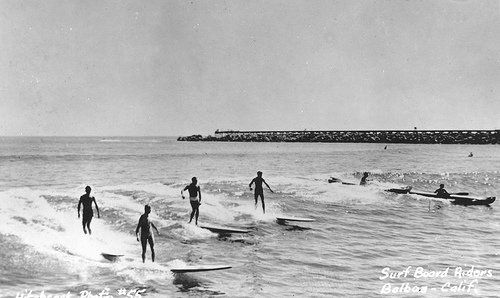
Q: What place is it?
A: It is an ocean.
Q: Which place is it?
A: It is an ocean.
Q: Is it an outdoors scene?
A: Yes, it is outdoors.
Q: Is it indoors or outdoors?
A: It is outdoors.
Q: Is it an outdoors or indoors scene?
A: It is outdoors.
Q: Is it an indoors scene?
A: No, it is outdoors.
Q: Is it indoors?
A: No, it is outdoors.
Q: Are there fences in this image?
A: No, there are no fences.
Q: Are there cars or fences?
A: No, there are no fences or cars.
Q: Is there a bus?
A: No, there are no buses.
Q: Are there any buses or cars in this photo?
A: No, there are no buses or cars.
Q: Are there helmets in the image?
A: No, there are no helmets.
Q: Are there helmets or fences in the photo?
A: No, there are no helmets or fences.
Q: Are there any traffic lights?
A: No, there are no traffic lights.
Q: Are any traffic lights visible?
A: No, there are no traffic lights.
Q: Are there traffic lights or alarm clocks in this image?
A: No, there are no traffic lights or alarm clocks.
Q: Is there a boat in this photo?
A: Yes, there is a boat.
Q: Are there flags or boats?
A: Yes, there is a boat.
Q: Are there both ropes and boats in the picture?
A: No, there is a boat but no ropes.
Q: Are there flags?
A: No, there are no flags.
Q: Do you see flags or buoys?
A: No, there are no flags or buoys.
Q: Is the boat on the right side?
A: Yes, the boat is on the right of the image.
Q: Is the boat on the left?
A: No, the boat is on the right of the image.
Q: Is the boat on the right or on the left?
A: The boat is on the right of the image.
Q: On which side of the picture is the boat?
A: The boat is on the right of the image.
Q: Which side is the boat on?
A: The boat is on the right of the image.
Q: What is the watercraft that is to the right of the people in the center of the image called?
A: The watercraft is a boat.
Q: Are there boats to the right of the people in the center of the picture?
A: Yes, there is a boat to the right of the people.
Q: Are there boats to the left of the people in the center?
A: No, the boat is to the right of the people.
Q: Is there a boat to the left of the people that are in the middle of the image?
A: No, the boat is to the right of the people.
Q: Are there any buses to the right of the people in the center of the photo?
A: No, there is a boat to the right of the people.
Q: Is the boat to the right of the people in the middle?
A: Yes, the boat is to the right of the people.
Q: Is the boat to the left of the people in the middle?
A: No, the boat is to the right of the people.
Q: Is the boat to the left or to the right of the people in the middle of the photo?
A: The boat is to the right of the people.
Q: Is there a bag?
A: No, there are no bags.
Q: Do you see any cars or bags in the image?
A: No, there are no bags or cars.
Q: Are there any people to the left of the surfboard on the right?
A: Yes, there are people to the left of the surf board.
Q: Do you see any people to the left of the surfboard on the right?
A: Yes, there are people to the left of the surf board.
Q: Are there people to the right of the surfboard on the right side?
A: No, the people are to the left of the surfboard.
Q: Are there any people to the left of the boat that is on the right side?
A: Yes, there are people to the left of the boat.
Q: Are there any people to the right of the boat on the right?
A: No, the people are to the left of the boat.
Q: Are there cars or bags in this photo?
A: No, there are no cars or bags.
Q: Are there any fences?
A: No, there are no fences.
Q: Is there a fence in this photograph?
A: No, there are no fences.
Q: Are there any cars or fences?
A: No, there are no fences or cars.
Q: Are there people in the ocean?
A: Yes, there are people in the ocean.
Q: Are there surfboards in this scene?
A: Yes, there is a surfboard.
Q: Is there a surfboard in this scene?
A: Yes, there is a surfboard.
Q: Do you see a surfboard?
A: Yes, there is a surfboard.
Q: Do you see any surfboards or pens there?
A: Yes, there is a surfboard.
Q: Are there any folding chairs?
A: No, there are no folding chairs.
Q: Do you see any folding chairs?
A: No, there are no folding chairs.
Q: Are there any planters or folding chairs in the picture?
A: No, there are no folding chairs or planters.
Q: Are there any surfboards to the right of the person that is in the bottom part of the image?
A: Yes, there is a surfboard to the right of the person.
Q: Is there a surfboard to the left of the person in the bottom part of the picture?
A: No, the surfboard is to the right of the person.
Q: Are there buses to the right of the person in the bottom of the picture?
A: No, there is a surfboard to the right of the person.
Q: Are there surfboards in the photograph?
A: Yes, there is a surfboard.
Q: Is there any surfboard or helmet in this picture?
A: Yes, there is a surfboard.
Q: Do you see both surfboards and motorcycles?
A: No, there is a surfboard but no motorcycles.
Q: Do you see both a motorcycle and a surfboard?
A: No, there is a surfboard but no motorcycles.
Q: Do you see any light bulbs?
A: No, there are no light bulbs.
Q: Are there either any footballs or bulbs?
A: No, there are no bulbs or footballs.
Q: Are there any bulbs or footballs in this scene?
A: No, there are no bulbs or footballs.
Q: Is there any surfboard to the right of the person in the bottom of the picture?
A: Yes, there is a surfboard to the right of the person.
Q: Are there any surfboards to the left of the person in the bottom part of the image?
A: No, the surfboard is to the right of the person.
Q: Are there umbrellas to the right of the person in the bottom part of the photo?
A: No, there is a surfboard to the right of the person.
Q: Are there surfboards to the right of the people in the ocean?
A: Yes, there is a surfboard to the right of the people.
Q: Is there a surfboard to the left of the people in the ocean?
A: No, the surfboard is to the right of the people.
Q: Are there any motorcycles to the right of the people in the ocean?
A: No, there is a surfboard to the right of the people.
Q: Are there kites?
A: No, there are no kites.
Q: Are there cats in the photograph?
A: No, there are no cats.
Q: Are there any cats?
A: No, there are no cats.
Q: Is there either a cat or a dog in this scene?
A: No, there are no cats or dogs.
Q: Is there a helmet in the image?
A: No, there are no helmets.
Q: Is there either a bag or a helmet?
A: No, there are no helmets or bags.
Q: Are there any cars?
A: No, there are no cars.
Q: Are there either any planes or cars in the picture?
A: No, there are no cars or planes.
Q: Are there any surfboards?
A: Yes, there is a surfboard.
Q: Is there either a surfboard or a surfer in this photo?
A: Yes, there is a surfboard.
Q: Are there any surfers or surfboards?
A: Yes, there is a surfboard.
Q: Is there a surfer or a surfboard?
A: Yes, there is a surfboard.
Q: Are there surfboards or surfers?
A: Yes, there is a surfboard.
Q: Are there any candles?
A: No, there are no candles.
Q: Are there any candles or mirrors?
A: No, there are no candles or mirrors.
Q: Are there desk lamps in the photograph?
A: No, there are no desk lamps.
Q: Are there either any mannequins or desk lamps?
A: No, there are no desk lamps or mannequins.